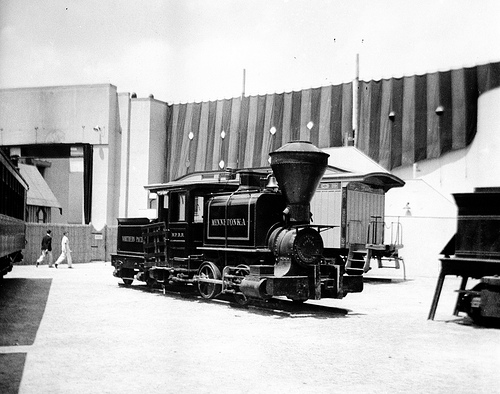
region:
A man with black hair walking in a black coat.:
[35, 227, 54, 266]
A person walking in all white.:
[53, 230, 74, 267]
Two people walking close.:
[36, 228, 72, 268]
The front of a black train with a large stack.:
[109, 139, 364, 309]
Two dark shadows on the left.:
[1, 279, 53, 393]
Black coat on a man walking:
[39, 232, 53, 253]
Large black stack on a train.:
[269, 141, 329, 224]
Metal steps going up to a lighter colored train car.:
[344, 244, 371, 276]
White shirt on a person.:
[60, 233, 70, 253]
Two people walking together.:
[38, 227, 74, 269]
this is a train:
[152, 191, 288, 282]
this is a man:
[40, 220, 138, 297]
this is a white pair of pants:
[57, 237, 62, 277]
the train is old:
[177, 140, 267, 363]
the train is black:
[149, 154, 311, 267]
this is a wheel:
[212, 277, 262, 309]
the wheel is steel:
[182, 226, 292, 333]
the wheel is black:
[212, 275, 272, 324]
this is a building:
[57, 108, 113, 158]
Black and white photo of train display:
[10, 27, 496, 389]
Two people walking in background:
[33, 227, 73, 269]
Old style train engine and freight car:
[108, 139, 368, 316]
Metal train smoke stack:
[265, 132, 329, 212]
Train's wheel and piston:
[192, 254, 274, 308]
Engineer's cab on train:
[144, 169, 239, 231]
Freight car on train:
[107, 205, 154, 289]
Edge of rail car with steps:
[305, 169, 408, 279]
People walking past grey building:
[1, 78, 114, 267]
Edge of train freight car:
[425, 181, 498, 334]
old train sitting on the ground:
[103, 139, 365, 310]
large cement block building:
[4, 82, 171, 270]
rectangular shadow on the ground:
[4, 270, 56, 385]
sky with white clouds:
[8, 5, 410, 87]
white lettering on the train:
[205, 216, 248, 229]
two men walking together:
[36, 225, 76, 270]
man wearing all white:
[51, 227, 78, 267]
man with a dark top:
[36, 230, 55, 266]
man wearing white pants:
[39, 227, 57, 264]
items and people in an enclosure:
[1, 53, 496, 392]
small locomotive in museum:
[145, 161, 323, 311]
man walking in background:
[58, 228, 72, 269]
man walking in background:
[40, 229, 54, 264]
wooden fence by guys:
[20, 226, 109, 263]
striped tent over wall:
[158, 101, 465, 156]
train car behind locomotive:
[324, 153, 396, 265]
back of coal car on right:
[423, 173, 498, 309]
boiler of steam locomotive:
[267, 138, 332, 266]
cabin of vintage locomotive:
[156, 191, 216, 258]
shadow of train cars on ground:
[13, 266, 59, 387]